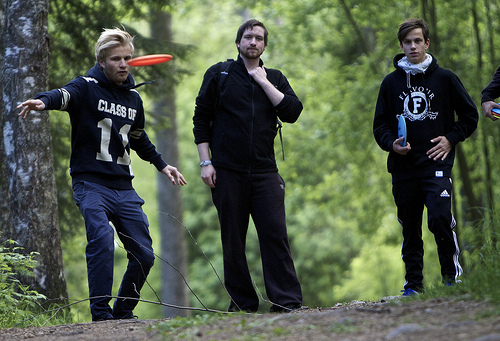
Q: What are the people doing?
A: Playing Frisbee golf.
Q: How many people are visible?
A: 4.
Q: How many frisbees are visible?
A: 3.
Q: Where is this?
A: In a forest.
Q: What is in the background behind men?
A: Greenery.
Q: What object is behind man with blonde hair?
A: Tree trunk.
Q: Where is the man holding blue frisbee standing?
A: Forest.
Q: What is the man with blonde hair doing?
A: Tossing frisbee.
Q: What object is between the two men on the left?
A: Tree trunk.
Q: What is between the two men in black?
A: Green tree.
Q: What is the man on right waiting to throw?
A: Frisbee.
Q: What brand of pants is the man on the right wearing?
A: Adidas.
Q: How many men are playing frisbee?
A: 3.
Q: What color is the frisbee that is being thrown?
A: Orange.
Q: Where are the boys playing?
A: In the woods.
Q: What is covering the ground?
A: Dirt.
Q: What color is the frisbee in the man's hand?
A: Blue.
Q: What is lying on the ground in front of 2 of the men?
A: A branch.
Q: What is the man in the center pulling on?
A: The neckline of his jacket.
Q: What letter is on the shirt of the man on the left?
A: F.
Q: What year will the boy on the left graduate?
A: 2011.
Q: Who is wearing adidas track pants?
A: The boy on the right.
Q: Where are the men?
A: The forest.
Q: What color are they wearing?
A: Black.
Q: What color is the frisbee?
A: Orange.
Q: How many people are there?
A: Three.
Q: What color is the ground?
A: Brown.